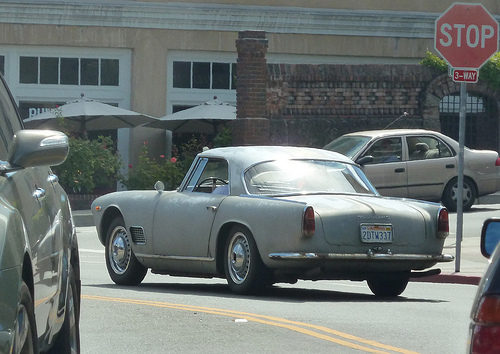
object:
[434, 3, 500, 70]
stop sign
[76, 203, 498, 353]
road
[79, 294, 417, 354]
lines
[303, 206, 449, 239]
tail lights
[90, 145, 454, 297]
car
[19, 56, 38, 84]
window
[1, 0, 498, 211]
building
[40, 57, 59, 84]
window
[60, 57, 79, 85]
window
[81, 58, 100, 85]
window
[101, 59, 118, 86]
window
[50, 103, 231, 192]
shrubs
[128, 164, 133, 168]
flowers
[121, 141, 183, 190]
plant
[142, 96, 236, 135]
umbrella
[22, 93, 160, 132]
umbrella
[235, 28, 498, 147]
wall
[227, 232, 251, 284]
hubcap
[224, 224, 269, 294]
tire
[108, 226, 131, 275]
hubcap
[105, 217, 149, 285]
tire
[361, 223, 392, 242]
license plate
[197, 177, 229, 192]
steering wheel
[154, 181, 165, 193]
side mirror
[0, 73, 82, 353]
car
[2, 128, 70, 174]
side mirror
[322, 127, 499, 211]
car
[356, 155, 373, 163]
side mirror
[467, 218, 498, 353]
vehicle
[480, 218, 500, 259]
side mirror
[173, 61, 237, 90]
windows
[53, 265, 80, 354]
wheels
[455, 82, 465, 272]
post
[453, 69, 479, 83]
3 way sign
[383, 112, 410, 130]
attenna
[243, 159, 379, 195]
back window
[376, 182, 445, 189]
stripe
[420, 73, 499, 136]
archway